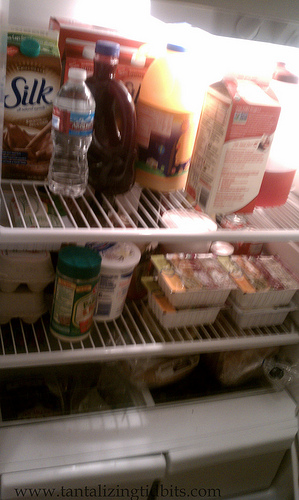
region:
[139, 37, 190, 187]
orange juice in the fridge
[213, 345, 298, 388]
bread in the fridge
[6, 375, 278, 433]
glass shelf in the bottom of the fridge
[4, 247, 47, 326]
two cartons of eggs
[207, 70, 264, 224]
a red and white carton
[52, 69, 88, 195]
a water bottle in the fridge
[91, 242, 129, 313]
a plastic container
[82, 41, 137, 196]
a brown bottle in the fridge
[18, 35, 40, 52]
a green cap on the milk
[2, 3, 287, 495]
a fridge full of food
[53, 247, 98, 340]
Parmesan cheese in the fridge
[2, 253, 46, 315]
cartons of eggs in the fridge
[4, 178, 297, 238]
a white shelf in the fridge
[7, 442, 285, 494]
white drawers in the fridge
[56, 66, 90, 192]
a bottle of water in the fridge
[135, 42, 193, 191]
a plastic jug of juice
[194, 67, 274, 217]
a carton in the fridge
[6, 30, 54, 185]
a carton of milk in the fridge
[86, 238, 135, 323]
a tub of yogurt in the fridge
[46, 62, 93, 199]
clear plastic water bottle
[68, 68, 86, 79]
white cap on the bottle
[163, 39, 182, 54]
blue cap on the top of the bottle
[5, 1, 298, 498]
food in the fridge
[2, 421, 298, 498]
two drawers at the bottom of the fridge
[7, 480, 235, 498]
website written in black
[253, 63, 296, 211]
jug with a little bit of red liquid in it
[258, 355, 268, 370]
tie around the plastic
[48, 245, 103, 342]
container of Parmesan cheese